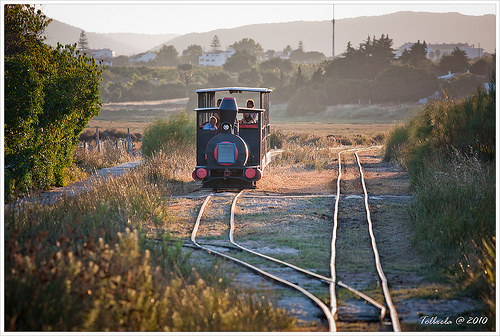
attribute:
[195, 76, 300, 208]
train — black, red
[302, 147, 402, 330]
tracks — merging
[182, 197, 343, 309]
tracks — merging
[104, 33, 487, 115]
trees — healthy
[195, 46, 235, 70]
building — tall, white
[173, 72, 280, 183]
trolley — black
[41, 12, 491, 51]
mountains — big, vast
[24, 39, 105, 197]
tree — leaves, green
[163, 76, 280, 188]
train — path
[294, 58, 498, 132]
hill — bush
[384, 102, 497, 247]
bush — hill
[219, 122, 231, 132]
light — white 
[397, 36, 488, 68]
building — white 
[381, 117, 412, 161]
bush — hill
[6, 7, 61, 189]
tree — tall, green